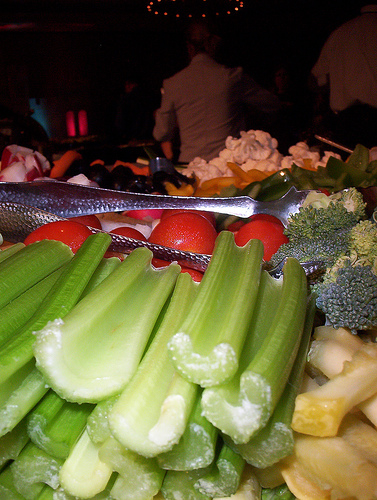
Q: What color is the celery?
A: Green.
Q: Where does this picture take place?
A: At a party.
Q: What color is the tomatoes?
A: Red.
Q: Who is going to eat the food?
A: Men and women.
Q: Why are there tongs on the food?
A: The tongs are for people to grab the food with.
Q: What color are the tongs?
A: Gray.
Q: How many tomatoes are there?
A: Six.